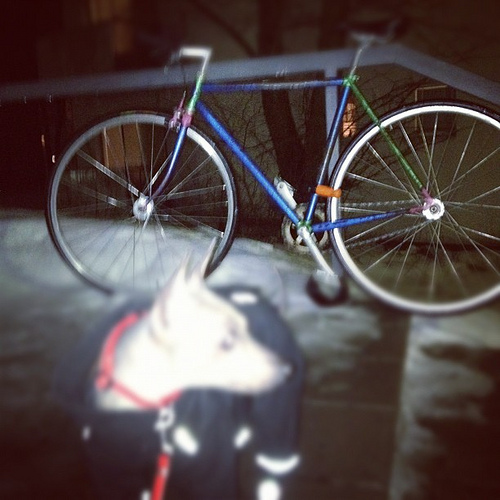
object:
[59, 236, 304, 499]
dog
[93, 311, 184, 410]
collar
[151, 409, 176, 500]
leash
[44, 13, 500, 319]
bicycle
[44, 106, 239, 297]
front tire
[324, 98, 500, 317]
rear tire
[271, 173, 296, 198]
pedal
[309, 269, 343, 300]
pedal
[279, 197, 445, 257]
chain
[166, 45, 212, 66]
handlebars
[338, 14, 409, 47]
seat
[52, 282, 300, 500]
clothes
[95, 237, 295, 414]
hair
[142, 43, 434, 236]
frame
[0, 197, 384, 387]
snow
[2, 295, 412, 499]
porch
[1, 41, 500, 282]
railing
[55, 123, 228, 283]
spokes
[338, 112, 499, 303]
spokes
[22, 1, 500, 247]
house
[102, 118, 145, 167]
window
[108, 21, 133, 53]
window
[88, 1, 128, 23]
window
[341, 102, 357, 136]
window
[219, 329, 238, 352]
eye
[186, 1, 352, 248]
tree